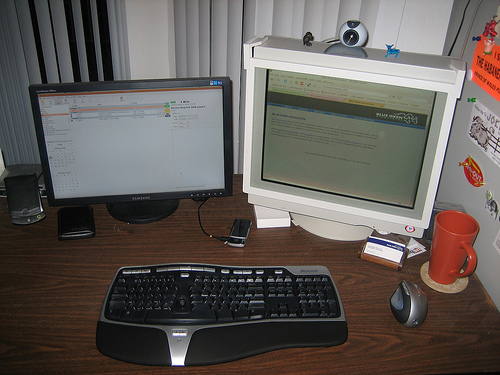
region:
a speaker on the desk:
[6, 172, 43, 219]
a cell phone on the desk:
[225, 215, 245, 250]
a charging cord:
[198, 210, 228, 242]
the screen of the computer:
[35, 81, 225, 196]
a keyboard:
[95, 262, 340, 358]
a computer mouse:
[395, 280, 425, 315]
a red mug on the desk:
[430, 215, 480, 282]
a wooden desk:
[5, 190, 495, 365]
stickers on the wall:
[460, 155, 497, 205]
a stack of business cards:
[363, 232, 405, 264]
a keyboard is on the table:
[88, 250, 355, 369]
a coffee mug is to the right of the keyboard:
[419, 205, 483, 297]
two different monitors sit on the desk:
[30, 35, 440, 237]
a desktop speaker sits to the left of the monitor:
[1, 168, 46, 233]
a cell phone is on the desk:
[198, 199, 259, 255]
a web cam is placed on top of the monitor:
[331, 18, 374, 53]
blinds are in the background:
[7, 8, 442, 155]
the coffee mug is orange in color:
[426, 200, 479, 286]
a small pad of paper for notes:
[242, 188, 298, 234]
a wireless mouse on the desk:
[388, 278, 430, 333]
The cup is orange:
[397, 205, 498, 310]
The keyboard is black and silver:
[93, 242, 361, 368]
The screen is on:
[29, 68, 257, 220]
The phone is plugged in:
[211, 198, 271, 275]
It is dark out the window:
[20, 14, 137, 104]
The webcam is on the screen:
[328, 15, 376, 58]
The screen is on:
[224, 59, 456, 215]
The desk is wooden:
[11, 245, 141, 365]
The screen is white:
[111, 122, 178, 181]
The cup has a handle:
[420, 210, 487, 295]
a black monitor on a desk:
[30, 78, 235, 206]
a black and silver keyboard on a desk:
[96, 262, 348, 367]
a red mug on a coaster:
[429, 208, 479, 286]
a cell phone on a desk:
[228, 215, 252, 246]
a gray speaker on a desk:
[5, 173, 44, 225]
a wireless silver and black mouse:
[391, 279, 430, 328]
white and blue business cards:
[363, 232, 405, 262]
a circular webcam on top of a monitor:
[337, 19, 369, 50]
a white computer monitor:
[241, 32, 464, 244]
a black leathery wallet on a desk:
[55, 204, 93, 239]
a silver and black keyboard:
[94, 262, 351, 374]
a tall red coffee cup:
[423, 205, 485, 294]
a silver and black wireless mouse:
[383, 275, 432, 323]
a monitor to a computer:
[21, 75, 235, 215]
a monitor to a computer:
[246, 50, 466, 226]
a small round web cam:
[328, 13, 377, 58]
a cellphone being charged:
[193, 203, 255, 254]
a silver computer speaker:
[0, 173, 45, 235]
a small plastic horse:
[383, 40, 407, 61]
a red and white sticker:
[452, 148, 487, 190]